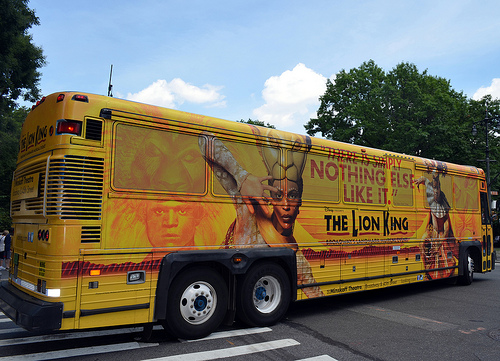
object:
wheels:
[158, 259, 297, 330]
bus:
[10, 93, 495, 289]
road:
[347, 315, 434, 345]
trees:
[331, 61, 481, 141]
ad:
[284, 147, 416, 241]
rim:
[177, 281, 219, 325]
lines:
[208, 346, 337, 361]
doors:
[480, 183, 495, 272]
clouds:
[140, 76, 316, 114]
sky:
[34, 7, 499, 113]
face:
[272, 176, 300, 226]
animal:
[418, 150, 453, 276]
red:
[303, 142, 414, 204]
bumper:
[1, 285, 59, 329]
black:
[323, 210, 408, 237]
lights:
[51, 117, 85, 135]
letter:
[332, 214, 346, 234]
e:
[342, 214, 350, 229]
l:
[349, 209, 359, 236]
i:
[357, 216, 363, 230]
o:
[362, 213, 371, 232]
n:
[372, 216, 379, 229]